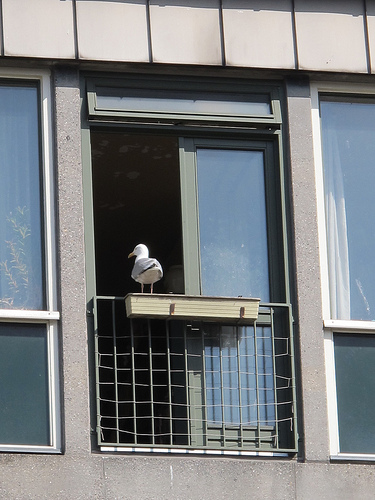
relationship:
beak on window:
[128, 243, 164, 293] [72, 83, 284, 462]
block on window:
[125, 291, 261, 324] [74, 80, 299, 339]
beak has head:
[128, 243, 164, 293] [132, 242, 148, 257]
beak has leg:
[128, 243, 164, 293] [150, 283, 153, 293]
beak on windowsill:
[128, 243, 164, 293] [88, 288, 305, 463]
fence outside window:
[88, 294, 299, 457] [78, 67, 307, 461]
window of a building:
[78, 67, 307, 461] [3, 3, 371, 497]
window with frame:
[3, 73, 67, 453] [32, 74, 363, 490]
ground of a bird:
[323, 118, 331, 140] [109, 224, 165, 294]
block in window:
[105, 277, 272, 330] [69, 112, 296, 471]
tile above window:
[2, 0, 373, 77] [88, 121, 289, 360]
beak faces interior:
[128, 243, 164, 293] [98, 173, 186, 288]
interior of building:
[98, 173, 186, 288] [7, 79, 370, 477]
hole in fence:
[96, 338, 131, 374] [100, 316, 213, 451]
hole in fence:
[98, 396, 122, 424] [94, 308, 292, 447]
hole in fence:
[123, 400, 138, 417] [88, 287, 318, 468]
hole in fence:
[133, 368, 153, 384] [86, 291, 304, 462]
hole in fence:
[184, 352, 205, 372] [86, 291, 304, 462]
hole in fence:
[163, 351, 199, 389] [81, 277, 307, 452]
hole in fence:
[220, 353, 239, 371] [94, 308, 292, 447]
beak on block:
[128, 243, 164, 293] [125, 291, 261, 324]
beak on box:
[128, 243, 164, 293] [122, 290, 263, 329]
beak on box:
[128, 243, 164, 293] [120, 287, 272, 325]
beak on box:
[128, 243, 164, 293] [106, 284, 273, 339]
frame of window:
[0, 61, 62, 450] [0, 80, 47, 445]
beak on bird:
[118, 240, 171, 287] [106, 232, 168, 296]